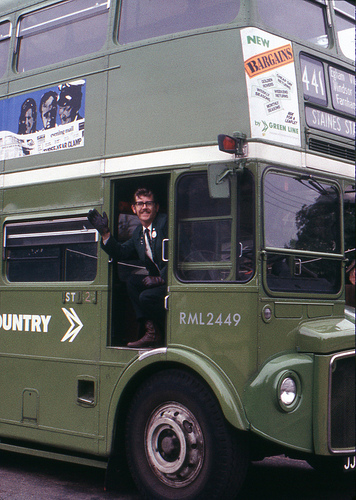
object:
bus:
[1, 4, 354, 475]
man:
[92, 189, 166, 345]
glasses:
[132, 200, 140, 205]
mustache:
[138, 206, 152, 214]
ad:
[0, 74, 85, 165]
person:
[58, 79, 87, 148]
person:
[39, 90, 58, 155]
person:
[19, 100, 38, 159]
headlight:
[275, 371, 298, 407]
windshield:
[259, 165, 342, 296]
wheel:
[131, 371, 233, 492]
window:
[264, 169, 340, 289]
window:
[178, 174, 251, 276]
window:
[8, 227, 95, 279]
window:
[117, 6, 248, 36]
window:
[14, 15, 108, 55]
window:
[252, 5, 331, 46]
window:
[0, 24, 12, 78]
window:
[329, 10, 354, 62]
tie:
[147, 227, 151, 257]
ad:
[240, 28, 303, 146]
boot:
[125, 323, 157, 346]